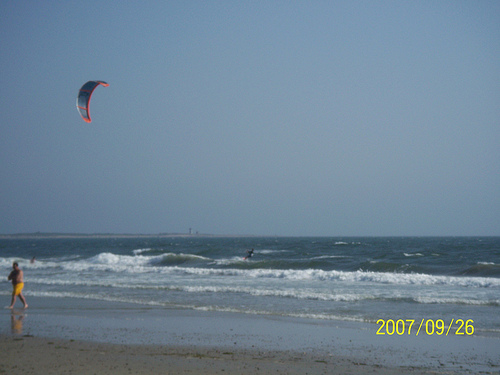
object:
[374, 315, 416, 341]
year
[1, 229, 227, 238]
coast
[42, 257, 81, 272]
white waves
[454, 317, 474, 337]
number 26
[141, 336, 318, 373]
footprints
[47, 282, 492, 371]
sand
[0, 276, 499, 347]
shore water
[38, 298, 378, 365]
shore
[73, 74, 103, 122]
object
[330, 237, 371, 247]
wave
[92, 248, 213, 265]
wave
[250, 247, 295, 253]
wave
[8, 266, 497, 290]
wave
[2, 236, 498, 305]
ocean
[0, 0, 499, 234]
sky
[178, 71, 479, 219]
clouds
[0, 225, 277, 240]
land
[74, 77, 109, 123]
kite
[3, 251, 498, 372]
beach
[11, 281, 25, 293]
yellow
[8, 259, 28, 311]
man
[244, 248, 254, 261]
man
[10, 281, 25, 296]
shorts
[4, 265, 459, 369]
ground